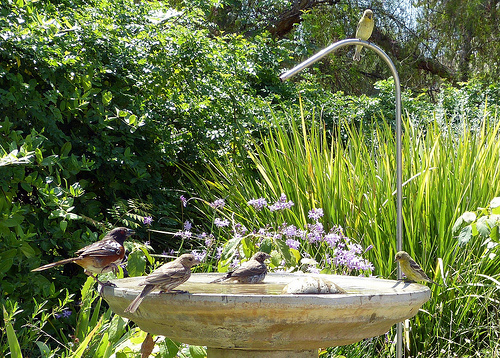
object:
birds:
[123, 251, 274, 315]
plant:
[424, 228, 497, 353]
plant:
[4, 284, 127, 355]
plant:
[428, 77, 495, 159]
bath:
[97, 35, 430, 357]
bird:
[30, 227, 136, 288]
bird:
[353, 8, 375, 61]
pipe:
[315, 39, 466, 253]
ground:
[402, 154, 472, 235]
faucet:
[276, 36, 405, 358]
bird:
[208, 252, 273, 284]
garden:
[0, 0, 499, 358]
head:
[110, 226, 136, 242]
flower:
[177, 192, 376, 277]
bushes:
[206, 95, 499, 358]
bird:
[123, 253, 202, 314]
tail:
[121, 284, 151, 316]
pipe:
[277, 34, 407, 356]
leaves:
[391, 85, 472, 202]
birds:
[27, 227, 200, 314]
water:
[232, 283, 266, 290]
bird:
[393, 251, 442, 287]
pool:
[91, 268, 431, 357]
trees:
[2, 2, 482, 228]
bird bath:
[91, 259, 431, 354]